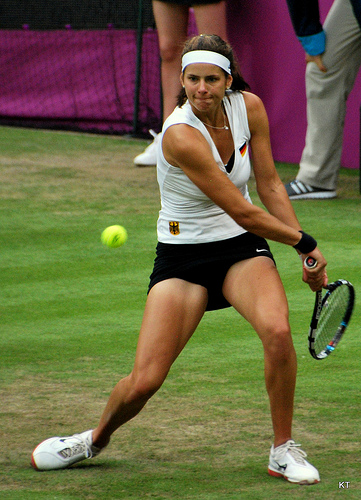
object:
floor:
[277, 145, 300, 172]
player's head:
[179, 34, 234, 114]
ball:
[101, 224, 128, 247]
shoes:
[32, 428, 110, 471]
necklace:
[200, 108, 229, 130]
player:
[30, 35, 328, 484]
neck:
[191, 101, 224, 122]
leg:
[285, 0, 361, 201]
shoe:
[267, 439, 320, 485]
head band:
[181, 49, 231, 75]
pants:
[295, 0, 361, 189]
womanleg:
[222, 252, 298, 448]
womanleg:
[91, 279, 211, 445]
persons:
[132, 0, 232, 167]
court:
[0, 120, 360, 500]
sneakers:
[30, 430, 320, 485]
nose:
[198, 81, 209, 95]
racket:
[302, 256, 354, 361]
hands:
[302, 238, 329, 293]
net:
[0, 2, 158, 137]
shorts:
[147, 231, 277, 312]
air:
[43, 248, 135, 349]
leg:
[223, 249, 320, 485]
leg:
[31, 262, 209, 469]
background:
[0, 0, 360, 115]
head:
[180, 34, 233, 113]